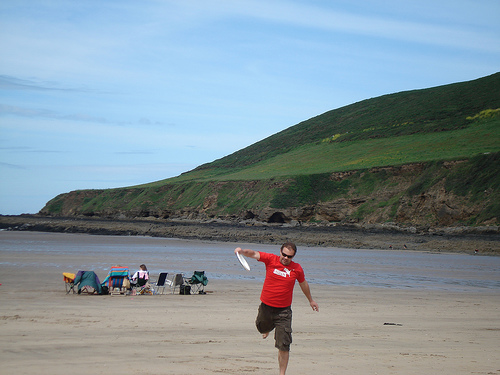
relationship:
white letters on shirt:
[273, 265, 287, 277] [256, 250, 306, 308]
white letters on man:
[273, 265, 287, 277] [233, 239, 318, 374]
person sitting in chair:
[130, 261, 147, 280] [129, 271, 148, 296]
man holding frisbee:
[236, 225, 311, 355] [232, 243, 252, 274]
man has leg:
[232, 242, 319, 375] [251, 303, 275, 341]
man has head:
[232, 242, 319, 375] [276, 242, 300, 262]